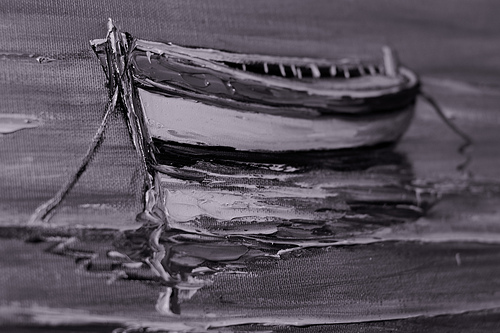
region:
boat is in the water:
[29, 42, 426, 178]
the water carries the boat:
[45, 78, 451, 264]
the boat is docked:
[43, 58, 135, 204]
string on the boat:
[37, 38, 150, 197]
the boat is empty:
[82, 7, 432, 152]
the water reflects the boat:
[97, 147, 419, 284]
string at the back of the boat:
[410, 85, 477, 140]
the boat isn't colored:
[27, 13, 457, 315]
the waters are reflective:
[1, 193, 423, 310]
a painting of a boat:
[23, 9, 489, 306]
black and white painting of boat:
[18, 12, 488, 325]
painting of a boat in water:
[23, 7, 497, 292]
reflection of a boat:
[78, 156, 467, 317]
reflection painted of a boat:
[57, 89, 484, 326]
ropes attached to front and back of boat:
[24, 15, 497, 300]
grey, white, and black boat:
[84, 15, 461, 217]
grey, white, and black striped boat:
[60, 0, 464, 296]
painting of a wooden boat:
[43, 20, 498, 307]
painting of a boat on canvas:
[13, 8, 490, 308]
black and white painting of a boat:
[2, 7, 499, 332]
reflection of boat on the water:
[128, 154, 403, 290]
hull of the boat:
[111, 36, 416, 161]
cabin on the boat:
[197, 44, 387, 86]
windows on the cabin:
[219, 54, 390, 79]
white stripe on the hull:
[138, 96, 415, 150]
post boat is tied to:
[101, 33, 158, 170]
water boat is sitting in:
[8, 62, 496, 332]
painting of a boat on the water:
[5, 4, 496, 331]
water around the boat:
[20, 87, 498, 298]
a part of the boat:
[59, 12, 179, 200]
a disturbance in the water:
[83, 208, 271, 318]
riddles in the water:
[249, 220, 369, 317]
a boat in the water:
[75, 10, 476, 190]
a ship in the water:
[63, 12, 497, 219]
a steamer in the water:
[56, 11, 494, 228]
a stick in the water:
[8, 108, 195, 254]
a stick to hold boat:
[401, 78, 489, 143]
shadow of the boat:
[176, 159, 344, 316]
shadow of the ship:
[166, 158, 331, 302]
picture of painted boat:
[37, 7, 486, 230]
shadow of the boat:
[170, 144, 437, 277]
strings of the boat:
[56, 96, 109, 196]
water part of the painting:
[203, 245, 383, 297]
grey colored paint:
[20, 27, 105, 118]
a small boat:
[88, 13, 437, 187]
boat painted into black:
[169, 142, 286, 173]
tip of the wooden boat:
[101, 18, 130, 38]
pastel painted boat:
[27, 4, 497, 277]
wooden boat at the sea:
[68, 22, 433, 186]